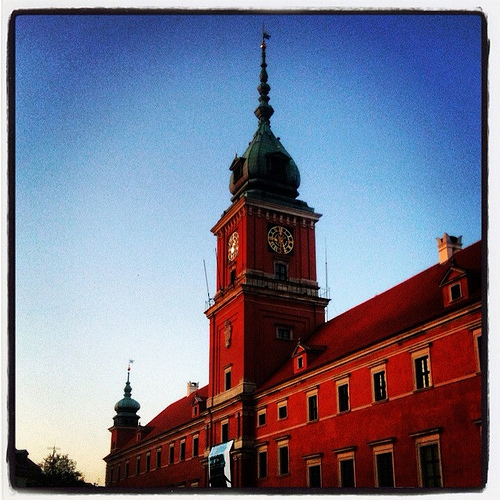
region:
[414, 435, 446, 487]
window on a building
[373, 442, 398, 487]
window on a building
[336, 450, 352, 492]
window on a building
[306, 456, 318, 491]
window on a building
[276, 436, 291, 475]
window on a building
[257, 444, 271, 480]
window on a building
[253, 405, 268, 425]
window on a building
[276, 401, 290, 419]
window on a building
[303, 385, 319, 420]
window on a building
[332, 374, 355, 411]
window on a building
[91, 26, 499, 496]
large structure made out of red bricks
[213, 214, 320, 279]
clocks on all faces of the top structure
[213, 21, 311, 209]
pointy dome at the top of the structure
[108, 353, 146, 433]
another pointy dome structure in the distance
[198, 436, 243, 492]
poster hanging from the front face of the building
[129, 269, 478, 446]
windows emerging from the roof structure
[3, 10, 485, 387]
tinted blue sky in the back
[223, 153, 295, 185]
openings in the dome structure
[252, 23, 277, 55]
flag at the top of the dome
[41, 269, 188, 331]
the sky is blue and white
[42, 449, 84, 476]
the trees is green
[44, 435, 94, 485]
the trees is in the back of the building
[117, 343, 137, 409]
there was a point on the buiding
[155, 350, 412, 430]
the building is red in color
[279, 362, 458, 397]
the building has alot of windows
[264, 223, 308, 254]
the clock is at the top of the church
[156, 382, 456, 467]
the building is big and long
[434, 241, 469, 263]
a chimmey was on top of the house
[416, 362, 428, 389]
the windows has wht curtain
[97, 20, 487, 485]
red brick building with tower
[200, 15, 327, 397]
tower with tow white clock faces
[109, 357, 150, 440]
smll green turret on red building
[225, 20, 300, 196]
large green turret on red building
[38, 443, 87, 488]
gren tree sihouetted ion background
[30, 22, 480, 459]
blue clear sunny sky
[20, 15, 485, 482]
grainy color soaked photograph taken during the daytime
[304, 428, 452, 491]
row of four rectangular windows in building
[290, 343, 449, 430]
row of four rectangular windows in building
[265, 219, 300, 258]
round white clock face with gold dials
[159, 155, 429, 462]
a picture of a tall building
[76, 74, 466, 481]
the building is islamic shaped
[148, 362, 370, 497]
the building is red in color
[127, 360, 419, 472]
the buildinh=g has ,many windows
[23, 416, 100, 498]
trees are beside the building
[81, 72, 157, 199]
the sky i clear blue incolor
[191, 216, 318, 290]
two clocks are on the wall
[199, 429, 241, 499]
a banner is fitted on the building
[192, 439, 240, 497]
the banner os white in color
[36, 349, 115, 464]
the sky is coverd of clouds